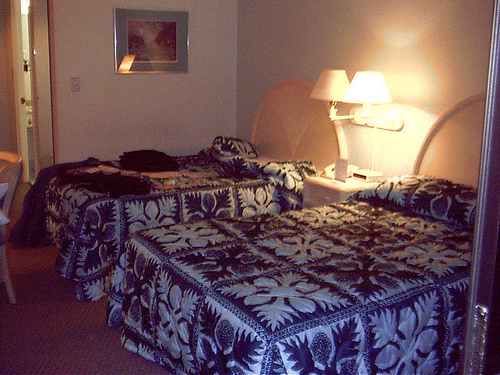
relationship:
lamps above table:
[308, 68, 395, 182] [301, 161, 385, 206]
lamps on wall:
[313, 75, 409, 167] [279, 29, 386, 76]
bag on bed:
[115, 149, 179, 172] [40, 75, 350, 302]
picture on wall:
[99, 57, 212, 79] [47, 27, 213, 174]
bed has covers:
[171, 204, 456, 355] [137, 221, 430, 336]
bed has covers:
[53, 140, 228, 225] [41, 134, 317, 306]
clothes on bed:
[14, 146, 194, 238] [49, 70, 349, 250]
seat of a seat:
[1, 122, 51, 311] [0, 150, 27, 304]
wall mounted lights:
[400, 55, 455, 104] [337, 72, 414, 124]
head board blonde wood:
[412, 92, 487, 189] [446, 115, 492, 155]